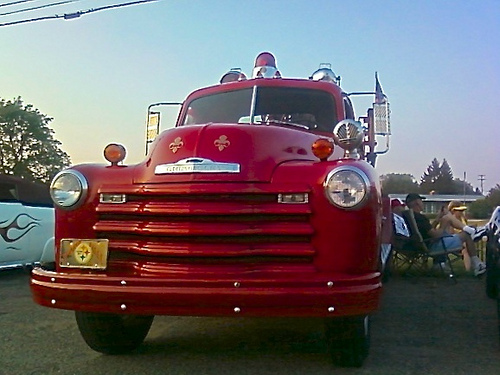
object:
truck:
[27, 49, 396, 368]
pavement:
[1, 271, 500, 372]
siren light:
[252, 52, 280, 79]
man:
[401, 191, 427, 256]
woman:
[428, 196, 485, 277]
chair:
[391, 227, 459, 285]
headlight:
[47, 167, 91, 213]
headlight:
[324, 163, 372, 212]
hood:
[51, 120, 349, 187]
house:
[382, 194, 490, 221]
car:
[2, 170, 55, 270]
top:
[1, 176, 53, 204]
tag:
[55, 233, 112, 271]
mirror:
[373, 103, 392, 137]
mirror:
[147, 112, 159, 142]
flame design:
[1, 212, 45, 243]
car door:
[1, 203, 47, 267]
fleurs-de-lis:
[167, 135, 187, 154]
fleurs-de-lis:
[212, 135, 232, 154]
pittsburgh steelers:
[73, 242, 94, 264]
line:
[1, 0, 78, 15]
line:
[1, 2, 32, 11]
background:
[2, 3, 497, 276]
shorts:
[421, 234, 465, 256]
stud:
[329, 307, 335, 314]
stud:
[233, 305, 242, 318]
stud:
[121, 305, 125, 311]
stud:
[50, 300, 57, 308]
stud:
[233, 281, 241, 288]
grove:
[89, 253, 316, 268]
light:
[218, 69, 249, 83]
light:
[308, 66, 342, 86]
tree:
[1, 90, 73, 206]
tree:
[422, 156, 446, 194]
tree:
[434, 157, 455, 195]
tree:
[380, 173, 419, 194]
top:
[2, 97, 73, 162]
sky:
[162, 2, 499, 52]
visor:
[448, 202, 471, 213]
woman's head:
[446, 198, 469, 218]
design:
[1, 212, 44, 254]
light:
[102, 142, 128, 164]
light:
[309, 138, 338, 160]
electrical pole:
[474, 174, 489, 199]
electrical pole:
[460, 167, 469, 196]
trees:
[384, 171, 419, 191]